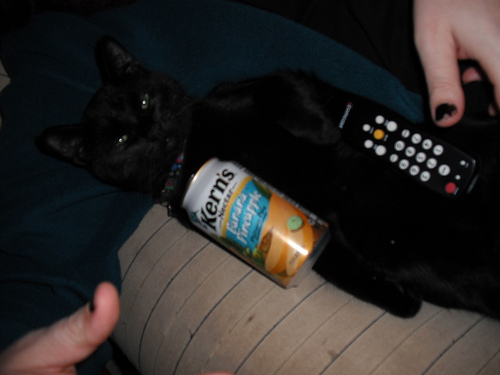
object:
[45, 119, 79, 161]
ear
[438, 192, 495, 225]
ground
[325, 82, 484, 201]
cordless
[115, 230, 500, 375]
fabric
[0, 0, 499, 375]
person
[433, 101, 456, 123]
nail polish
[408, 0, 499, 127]
hand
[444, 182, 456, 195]
red button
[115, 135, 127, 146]
eyes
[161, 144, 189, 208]
collar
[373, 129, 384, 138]
button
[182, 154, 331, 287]
can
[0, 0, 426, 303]
fabric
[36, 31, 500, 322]
cat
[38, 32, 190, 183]
head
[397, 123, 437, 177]
buttons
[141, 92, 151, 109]
eyes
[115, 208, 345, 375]
stripes